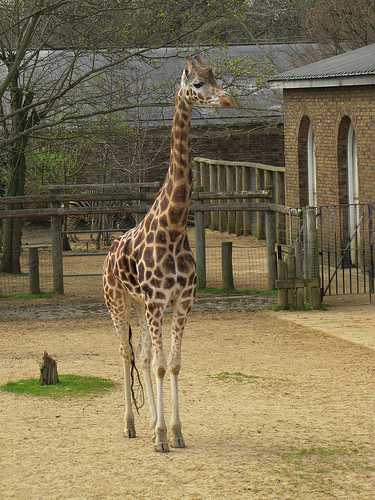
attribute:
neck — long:
[143, 78, 194, 234]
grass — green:
[0, 372, 122, 404]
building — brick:
[263, 46, 363, 273]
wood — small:
[33, 349, 64, 385]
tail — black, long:
[127, 308, 150, 421]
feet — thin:
[123, 411, 191, 452]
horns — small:
[183, 55, 206, 69]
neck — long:
[167, 100, 194, 192]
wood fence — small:
[282, 205, 320, 281]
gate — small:
[307, 204, 362, 303]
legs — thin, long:
[113, 310, 190, 449]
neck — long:
[166, 126, 194, 213]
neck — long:
[171, 115, 192, 188]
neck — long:
[172, 103, 190, 176]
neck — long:
[172, 100, 188, 194]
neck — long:
[173, 99, 192, 197]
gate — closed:
[303, 201, 363, 310]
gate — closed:
[307, 202, 362, 289]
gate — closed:
[311, 201, 362, 291]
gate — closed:
[307, 196, 361, 297]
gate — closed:
[315, 203, 361, 284]